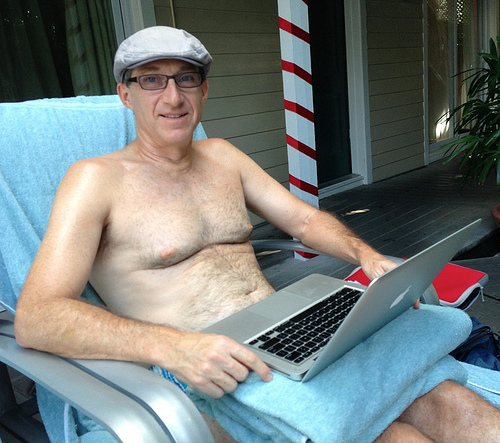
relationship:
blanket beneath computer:
[191, 319, 471, 439] [189, 214, 482, 385]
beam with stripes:
[266, 0, 321, 261] [276, 7, 313, 197]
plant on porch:
[432, 49, 480, 200] [377, 140, 482, 225]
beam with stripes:
[266, 0, 321, 261] [268, 0, 321, 260]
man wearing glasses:
[13, 24, 498, 440] [122, 69, 212, 99]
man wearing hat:
[13, 24, 498, 440] [103, 20, 221, 77]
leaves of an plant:
[465, 100, 483, 149] [440, 36, 484, 202]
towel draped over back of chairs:
[0, 92, 500, 441] [0, 90, 473, 440]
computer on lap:
[189, 214, 481, 381] [133, 313, 461, 428]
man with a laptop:
[13, 24, 498, 440] [187, 188, 483, 389]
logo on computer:
[382, 279, 417, 312] [179, 219, 478, 390]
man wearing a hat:
[13, 24, 498, 440] [103, 18, 215, 86]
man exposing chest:
[13, 24, 498, 440] [117, 179, 271, 319]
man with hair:
[13, 24, 498, 440] [137, 171, 240, 296]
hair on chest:
[137, 171, 240, 296] [117, 179, 271, 319]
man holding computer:
[13, 24, 498, 440] [189, 214, 482, 385]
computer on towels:
[189, 214, 482, 385] [197, 302, 474, 441]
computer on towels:
[189, 214, 482, 385] [172, 312, 471, 432]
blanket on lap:
[191, 303, 472, 443] [192, 317, 452, 439]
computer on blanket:
[189, 214, 482, 385] [191, 303, 472, 443]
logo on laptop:
[388, 283, 413, 310] [204, 217, 482, 382]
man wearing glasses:
[13, 24, 498, 440] [124, 66, 207, 92]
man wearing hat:
[13, 24, 498, 440] [112, 26, 212, 77]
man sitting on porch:
[13, 24, 498, 440] [249, 155, 499, 291]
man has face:
[13, 24, 498, 440] [131, 59, 205, 144]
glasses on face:
[120, 69, 207, 90] [131, 59, 205, 144]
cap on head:
[113, 24, 217, 88] [110, 24, 212, 148]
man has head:
[13, 24, 498, 440] [110, 24, 212, 148]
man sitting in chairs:
[13, 24, 498, 440] [0, 90, 500, 443]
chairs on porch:
[0, 90, 500, 443] [249, 155, 499, 291]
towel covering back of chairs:
[0, 92, 500, 441] [0, 90, 500, 443]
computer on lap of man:
[189, 214, 482, 385] [13, 24, 498, 440]